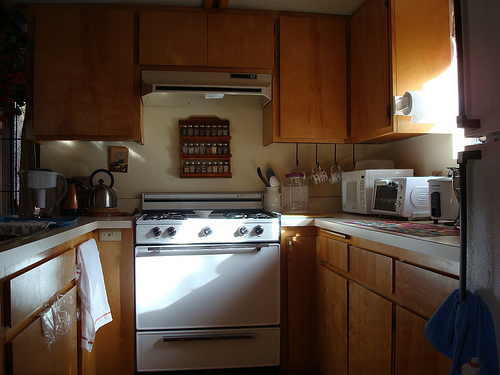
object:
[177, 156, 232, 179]
shelf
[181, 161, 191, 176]
spices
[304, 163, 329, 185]
mugs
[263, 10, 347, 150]
cabinet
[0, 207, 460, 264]
counter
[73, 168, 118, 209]
kettle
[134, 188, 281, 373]
stove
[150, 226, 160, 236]
knobs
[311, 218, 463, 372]
cabinets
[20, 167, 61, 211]
pitcher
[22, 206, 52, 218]
water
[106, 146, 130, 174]
picture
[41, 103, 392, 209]
wall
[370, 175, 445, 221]
toaster oven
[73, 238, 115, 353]
dish towel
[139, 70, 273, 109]
range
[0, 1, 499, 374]
kitchen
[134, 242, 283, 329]
door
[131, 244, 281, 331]
oven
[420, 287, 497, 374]
towel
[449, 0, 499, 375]
refrigerator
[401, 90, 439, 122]
paper towel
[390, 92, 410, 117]
dispenser